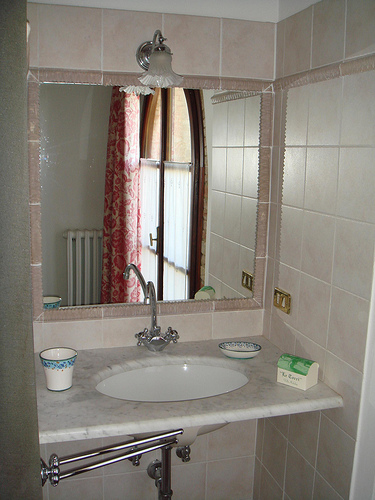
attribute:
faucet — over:
[137, 279, 180, 353]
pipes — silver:
[38, 418, 192, 498]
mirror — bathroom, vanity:
[39, 80, 261, 308]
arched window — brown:
[130, 84, 215, 296]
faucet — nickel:
[134, 282, 179, 351]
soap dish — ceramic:
[216, 336, 273, 360]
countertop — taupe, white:
[36, 347, 340, 445]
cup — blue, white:
[39, 345, 78, 393]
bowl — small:
[218, 340, 263, 360]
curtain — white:
[136, 157, 197, 305]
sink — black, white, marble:
[96, 361, 248, 403]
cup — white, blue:
[39, 338, 88, 394]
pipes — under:
[145, 443, 181, 498]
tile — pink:
[274, 80, 371, 392]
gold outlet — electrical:
[273, 286, 292, 314]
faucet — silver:
[134, 280, 187, 354]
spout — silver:
[143, 282, 158, 327]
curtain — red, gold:
[98, 84, 145, 304]